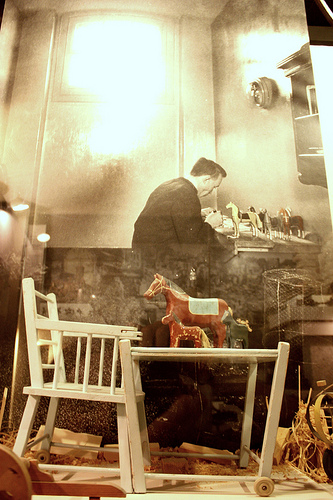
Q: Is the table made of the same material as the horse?
A: Yes, both the table and the horse are made of wood.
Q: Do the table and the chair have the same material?
A: Yes, both the table and the chair are made of wood.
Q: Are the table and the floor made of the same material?
A: Yes, both the table and the floor are made of wood.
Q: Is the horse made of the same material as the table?
A: Yes, both the horse and the table are made of wood.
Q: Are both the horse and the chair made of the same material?
A: Yes, both the horse and the chair are made of wood.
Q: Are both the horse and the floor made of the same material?
A: Yes, both the horse and the floor are made of wood.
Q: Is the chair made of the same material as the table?
A: Yes, both the chair and the table are made of wood.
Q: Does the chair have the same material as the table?
A: Yes, both the chair and the table are made of wood.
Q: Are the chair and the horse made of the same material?
A: Yes, both the chair and the horse are made of wood.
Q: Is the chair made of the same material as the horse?
A: Yes, both the chair and the horse are made of wood.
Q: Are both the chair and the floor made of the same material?
A: Yes, both the chair and the floor are made of wood.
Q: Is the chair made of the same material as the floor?
A: Yes, both the chair and the floor are made of wood.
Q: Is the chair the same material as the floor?
A: Yes, both the chair and the floor are made of wood.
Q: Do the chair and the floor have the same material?
A: Yes, both the chair and the floor are made of wood.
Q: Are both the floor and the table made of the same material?
A: Yes, both the floor and the table are made of wood.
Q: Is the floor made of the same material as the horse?
A: Yes, both the floor and the horse are made of wood.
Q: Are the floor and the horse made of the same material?
A: Yes, both the floor and the horse are made of wood.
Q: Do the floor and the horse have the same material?
A: Yes, both the floor and the horse are made of wood.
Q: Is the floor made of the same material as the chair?
A: Yes, both the floor and the chair are made of wood.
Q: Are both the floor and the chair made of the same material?
A: Yes, both the floor and the chair are made of wood.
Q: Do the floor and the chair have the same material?
A: Yes, both the floor and the chair are made of wood.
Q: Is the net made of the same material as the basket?
A: Yes, both the net and the basket are made of metal.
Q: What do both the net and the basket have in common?
A: The material, both the net and the basket are metallic.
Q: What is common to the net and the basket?
A: The material, both the net and the basket are metallic.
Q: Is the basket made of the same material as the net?
A: Yes, both the basket and the net are made of metal.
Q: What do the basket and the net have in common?
A: The material, both the basket and the net are metallic.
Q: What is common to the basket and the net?
A: The material, both the basket and the net are metallic.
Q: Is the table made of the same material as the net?
A: No, the table is made of wood and the net is made of metal.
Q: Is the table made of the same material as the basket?
A: No, the table is made of wood and the basket is made of metal.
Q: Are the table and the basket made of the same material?
A: No, the table is made of wood and the basket is made of metal.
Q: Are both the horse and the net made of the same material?
A: No, the horse is made of wood and the net is made of metal.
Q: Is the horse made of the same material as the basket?
A: No, the horse is made of wood and the basket is made of metal.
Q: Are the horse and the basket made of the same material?
A: No, the horse is made of wood and the basket is made of metal.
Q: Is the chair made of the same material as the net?
A: No, the chair is made of wood and the net is made of metal.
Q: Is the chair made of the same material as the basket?
A: No, the chair is made of wood and the basket is made of metal.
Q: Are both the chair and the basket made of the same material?
A: No, the chair is made of wood and the basket is made of metal.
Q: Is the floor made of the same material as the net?
A: No, the floor is made of wood and the net is made of metal.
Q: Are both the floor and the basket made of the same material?
A: No, the floor is made of wood and the basket is made of metal.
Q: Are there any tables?
A: Yes, there is a table.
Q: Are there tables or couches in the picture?
A: Yes, there is a table.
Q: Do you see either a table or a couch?
A: Yes, there is a table.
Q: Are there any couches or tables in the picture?
A: Yes, there is a table.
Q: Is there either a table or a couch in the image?
A: Yes, there is a table.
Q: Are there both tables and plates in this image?
A: No, there is a table but no plates.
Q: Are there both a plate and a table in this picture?
A: No, there is a table but no plates.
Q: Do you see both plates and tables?
A: No, there is a table but no plates.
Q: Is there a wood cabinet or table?
A: Yes, there is a wood table.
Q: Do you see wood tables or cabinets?
A: Yes, there is a wood table.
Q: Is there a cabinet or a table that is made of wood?
A: Yes, the table is made of wood.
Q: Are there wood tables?
A: Yes, there is a table that is made of wood.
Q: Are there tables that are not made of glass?
A: Yes, there is a table that is made of wood.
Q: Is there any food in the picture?
A: No, there is no food.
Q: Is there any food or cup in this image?
A: No, there are no food or cups.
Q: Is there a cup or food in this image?
A: No, there are no food or cups.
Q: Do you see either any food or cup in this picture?
A: No, there are no food or cups.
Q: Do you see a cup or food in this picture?
A: No, there are no food or cups.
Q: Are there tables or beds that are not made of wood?
A: No, there is a table but it is made of wood.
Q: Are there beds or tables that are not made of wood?
A: No, there is a table but it is made of wood.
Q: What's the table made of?
A: The table is made of wood.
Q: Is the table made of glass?
A: No, the table is made of wood.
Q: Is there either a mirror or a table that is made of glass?
A: No, there is a table but it is made of wood.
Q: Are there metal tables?
A: No, there is a table but it is made of wood.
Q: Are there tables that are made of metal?
A: No, there is a table but it is made of wood.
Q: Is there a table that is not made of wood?
A: No, there is a table but it is made of wood.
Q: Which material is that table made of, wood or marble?
A: The table is made of wood.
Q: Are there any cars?
A: No, there are no cars.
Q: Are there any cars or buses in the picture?
A: No, there are no cars or buses.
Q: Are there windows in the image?
A: Yes, there is a window.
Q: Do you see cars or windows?
A: Yes, there is a window.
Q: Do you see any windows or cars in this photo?
A: Yes, there is a window.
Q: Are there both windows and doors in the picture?
A: No, there is a window but no doors.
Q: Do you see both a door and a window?
A: No, there is a window but no doors.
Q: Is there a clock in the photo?
A: No, there are no clocks.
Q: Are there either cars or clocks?
A: No, there are no clocks or cars.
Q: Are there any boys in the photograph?
A: No, there are no boys.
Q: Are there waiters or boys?
A: No, there are no boys or waiters.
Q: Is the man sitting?
A: Yes, the man is sitting.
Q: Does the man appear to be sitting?
A: Yes, the man is sitting.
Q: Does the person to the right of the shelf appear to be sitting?
A: Yes, the man is sitting.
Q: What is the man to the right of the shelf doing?
A: The man is sitting.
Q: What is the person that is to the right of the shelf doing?
A: The man is sitting.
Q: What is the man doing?
A: The man is sitting.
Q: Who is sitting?
A: The man is sitting.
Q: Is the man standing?
A: No, the man is sitting.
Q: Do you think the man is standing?
A: No, the man is sitting.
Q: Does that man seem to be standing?
A: No, the man is sitting.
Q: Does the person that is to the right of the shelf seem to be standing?
A: No, the man is sitting.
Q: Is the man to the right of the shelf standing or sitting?
A: The man is sitting.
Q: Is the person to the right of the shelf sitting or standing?
A: The man is sitting.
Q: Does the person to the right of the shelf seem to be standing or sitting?
A: The man is sitting.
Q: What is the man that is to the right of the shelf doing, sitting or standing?
A: The man is sitting.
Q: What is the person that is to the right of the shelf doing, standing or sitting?
A: The man is sitting.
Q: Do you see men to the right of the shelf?
A: Yes, there is a man to the right of the shelf.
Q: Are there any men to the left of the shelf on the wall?
A: No, the man is to the right of the shelf.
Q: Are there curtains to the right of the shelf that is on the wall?
A: No, there is a man to the right of the shelf.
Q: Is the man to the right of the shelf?
A: Yes, the man is to the right of the shelf.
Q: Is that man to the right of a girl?
A: No, the man is to the right of the shelf.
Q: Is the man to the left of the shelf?
A: No, the man is to the right of the shelf.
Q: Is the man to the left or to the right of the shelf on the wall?
A: The man is to the right of the shelf.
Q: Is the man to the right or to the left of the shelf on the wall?
A: The man is to the right of the shelf.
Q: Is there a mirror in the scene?
A: No, there are no mirrors.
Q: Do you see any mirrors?
A: No, there are no mirrors.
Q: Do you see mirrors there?
A: No, there are no mirrors.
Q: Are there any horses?
A: Yes, there is a horse.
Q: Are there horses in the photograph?
A: Yes, there is a horse.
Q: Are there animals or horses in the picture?
A: Yes, there is a horse.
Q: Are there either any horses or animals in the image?
A: Yes, there is a horse.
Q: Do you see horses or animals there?
A: Yes, there is a horse.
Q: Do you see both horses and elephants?
A: No, there is a horse but no elephants.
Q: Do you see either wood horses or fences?
A: Yes, there is a wood horse.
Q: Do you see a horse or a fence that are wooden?
A: Yes, the horse is wooden.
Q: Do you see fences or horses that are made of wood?
A: Yes, the horse is made of wood.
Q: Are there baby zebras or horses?
A: Yes, there is a baby horse.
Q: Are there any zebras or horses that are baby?
A: Yes, the horse is a baby.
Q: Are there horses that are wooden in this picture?
A: Yes, there is a wood horse.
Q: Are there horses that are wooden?
A: Yes, there is a horse that is wooden.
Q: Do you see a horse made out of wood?
A: Yes, there is a horse that is made of wood.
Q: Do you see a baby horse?
A: Yes, there is a baby horse.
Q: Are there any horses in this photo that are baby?
A: Yes, there is a horse that is a baby.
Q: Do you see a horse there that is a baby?
A: Yes, there is a horse that is a baby.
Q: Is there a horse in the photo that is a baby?
A: Yes, there is a horse that is a baby.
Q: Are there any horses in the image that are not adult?
A: Yes, there is an baby horse.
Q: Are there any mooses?
A: No, there are no mooses.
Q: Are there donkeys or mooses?
A: No, there are no mooses or donkeys.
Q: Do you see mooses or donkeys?
A: No, there are no mooses or donkeys.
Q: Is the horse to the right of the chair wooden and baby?
A: Yes, the horse is wooden and baby.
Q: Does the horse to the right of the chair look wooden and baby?
A: Yes, the horse is wooden and baby.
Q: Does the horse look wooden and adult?
A: No, the horse is wooden but baby.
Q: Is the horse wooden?
A: Yes, the horse is wooden.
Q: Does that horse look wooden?
A: Yes, the horse is wooden.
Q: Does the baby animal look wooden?
A: Yes, the horse is wooden.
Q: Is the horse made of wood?
A: Yes, the horse is made of wood.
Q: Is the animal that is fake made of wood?
A: Yes, the horse is made of wood.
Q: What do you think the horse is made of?
A: The horse is made of wood.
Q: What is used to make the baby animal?
A: The horse is made of wood.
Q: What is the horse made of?
A: The horse is made of wood.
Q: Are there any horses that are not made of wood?
A: No, there is a horse but it is made of wood.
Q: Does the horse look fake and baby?
A: Yes, the horse is fake and baby.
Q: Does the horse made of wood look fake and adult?
A: No, the horse is fake but baby.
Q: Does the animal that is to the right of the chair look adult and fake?
A: No, the horse is fake but baby.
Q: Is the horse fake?
A: Yes, the horse is fake.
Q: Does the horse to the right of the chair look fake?
A: Yes, the horse is fake.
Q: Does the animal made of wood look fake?
A: Yes, the horse is fake.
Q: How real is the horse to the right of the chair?
A: The horse is fake.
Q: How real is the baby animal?
A: The horse is fake.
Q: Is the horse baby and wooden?
A: Yes, the horse is a baby and wooden.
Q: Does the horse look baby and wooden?
A: Yes, the horse is a baby and wooden.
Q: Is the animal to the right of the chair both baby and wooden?
A: Yes, the horse is a baby and wooden.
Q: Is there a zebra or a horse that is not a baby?
A: No, there is a horse but it is a baby.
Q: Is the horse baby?
A: Yes, the horse is a baby.